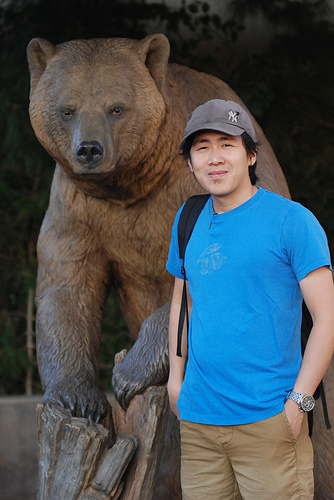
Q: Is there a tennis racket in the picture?
A: No, there are no rackets.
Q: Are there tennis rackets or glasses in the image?
A: No, there are no tennis rackets or glasses.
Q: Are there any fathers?
A: No, there are no fathers.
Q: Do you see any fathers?
A: No, there are no fathers.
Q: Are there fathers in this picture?
A: No, there are no fathers.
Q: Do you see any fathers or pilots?
A: No, there are no fathers or pilots.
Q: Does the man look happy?
A: Yes, the man is happy.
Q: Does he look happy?
A: Yes, the man is happy.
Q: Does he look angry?
A: No, the man is happy.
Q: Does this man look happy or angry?
A: The man is happy.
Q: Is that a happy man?
A: Yes, that is a happy man.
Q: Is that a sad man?
A: No, that is a happy man.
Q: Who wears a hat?
A: The man wears a hat.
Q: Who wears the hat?
A: The man wears a hat.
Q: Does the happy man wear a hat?
A: Yes, the man wears a hat.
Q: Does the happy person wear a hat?
A: Yes, the man wears a hat.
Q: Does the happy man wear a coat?
A: No, the man wears a hat.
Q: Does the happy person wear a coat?
A: No, the man wears a hat.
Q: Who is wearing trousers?
A: The man is wearing trousers.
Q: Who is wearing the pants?
A: The man is wearing trousers.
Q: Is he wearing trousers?
A: Yes, the man is wearing trousers.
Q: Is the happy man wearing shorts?
A: No, the man is wearing trousers.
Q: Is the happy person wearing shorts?
A: No, the man is wearing trousers.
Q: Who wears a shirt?
A: The man wears a shirt.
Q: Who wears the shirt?
A: The man wears a shirt.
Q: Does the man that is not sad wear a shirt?
A: Yes, the man wears a shirt.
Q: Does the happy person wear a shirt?
A: Yes, the man wears a shirt.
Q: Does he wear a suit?
A: No, the man wears a shirt.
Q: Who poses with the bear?
A: The man poses with the bear.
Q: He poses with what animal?
A: The man poses with the bear.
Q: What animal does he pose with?
A: The man poses with the bear.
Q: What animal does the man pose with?
A: The man poses with the bear.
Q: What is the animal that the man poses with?
A: The animal is a bear.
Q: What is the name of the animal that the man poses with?
A: The animal is a bear.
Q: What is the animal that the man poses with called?
A: The animal is a bear.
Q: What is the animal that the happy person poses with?
A: The animal is a bear.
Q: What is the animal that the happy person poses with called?
A: The animal is a bear.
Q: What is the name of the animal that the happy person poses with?
A: The animal is a bear.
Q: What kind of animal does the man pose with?
A: The man poses with the bear.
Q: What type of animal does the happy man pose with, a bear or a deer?
A: The man poses with a bear.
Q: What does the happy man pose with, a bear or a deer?
A: The man poses with a bear.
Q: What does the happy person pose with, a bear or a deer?
A: The man poses with a bear.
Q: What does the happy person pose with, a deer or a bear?
A: The man poses with a bear.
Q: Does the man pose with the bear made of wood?
A: Yes, the man poses with the bear.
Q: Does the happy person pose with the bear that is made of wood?
A: Yes, the man poses with the bear.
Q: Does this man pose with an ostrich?
A: No, the man poses with the bear.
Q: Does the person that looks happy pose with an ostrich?
A: No, the man poses with the bear.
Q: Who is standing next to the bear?
A: The man is standing next to the bear.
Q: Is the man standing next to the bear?
A: Yes, the man is standing next to the bear.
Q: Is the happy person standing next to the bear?
A: Yes, the man is standing next to the bear.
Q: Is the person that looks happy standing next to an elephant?
A: No, the man is standing next to the bear.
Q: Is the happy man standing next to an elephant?
A: No, the man is standing next to the bear.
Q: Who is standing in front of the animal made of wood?
A: The man is standing in front of the bear.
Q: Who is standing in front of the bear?
A: The man is standing in front of the bear.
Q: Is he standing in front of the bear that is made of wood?
A: Yes, the man is standing in front of the bear.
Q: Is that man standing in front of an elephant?
A: No, the man is standing in front of the bear.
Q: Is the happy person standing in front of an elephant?
A: No, the man is standing in front of the bear.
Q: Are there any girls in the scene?
A: No, there are no girls.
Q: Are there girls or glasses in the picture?
A: No, there are no girls or glasses.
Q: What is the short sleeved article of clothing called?
A: The clothing item is a shirt.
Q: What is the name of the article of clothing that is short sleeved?
A: The clothing item is a shirt.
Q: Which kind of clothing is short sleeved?
A: The clothing is a shirt.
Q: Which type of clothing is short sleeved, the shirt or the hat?
A: The shirt is short sleeved.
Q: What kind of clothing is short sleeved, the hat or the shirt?
A: The shirt is short sleeved.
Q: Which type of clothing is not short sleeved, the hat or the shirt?
A: The hat is not short sleeved.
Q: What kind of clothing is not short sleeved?
A: The clothing is a hat.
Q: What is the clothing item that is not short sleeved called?
A: The clothing item is a hat.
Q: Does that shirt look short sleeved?
A: Yes, the shirt is short sleeved.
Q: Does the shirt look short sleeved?
A: Yes, the shirt is short sleeved.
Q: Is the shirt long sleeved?
A: No, the shirt is short sleeved.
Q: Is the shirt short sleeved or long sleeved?
A: The shirt is short sleeved.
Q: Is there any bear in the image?
A: Yes, there is a bear.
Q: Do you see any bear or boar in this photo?
A: Yes, there is a bear.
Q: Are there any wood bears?
A: Yes, there is a wood bear.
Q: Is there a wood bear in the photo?
A: Yes, there is a wood bear.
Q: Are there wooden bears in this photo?
A: Yes, there is a wood bear.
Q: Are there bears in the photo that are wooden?
A: Yes, there is a bear that is wooden.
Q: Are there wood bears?
A: Yes, there is a bear that is made of wood.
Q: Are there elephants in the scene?
A: No, there are no elephants.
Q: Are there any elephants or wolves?
A: No, there are no elephants or wolves.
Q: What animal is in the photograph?
A: The animal is a bear.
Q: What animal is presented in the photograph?
A: The animal is a bear.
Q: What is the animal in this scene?
A: The animal is a bear.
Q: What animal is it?
A: The animal is a bear.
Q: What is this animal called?
A: That is a bear.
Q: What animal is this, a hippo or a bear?
A: That is a bear.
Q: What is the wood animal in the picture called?
A: The animal is a bear.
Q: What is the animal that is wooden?
A: The animal is a bear.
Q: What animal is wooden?
A: The animal is a bear.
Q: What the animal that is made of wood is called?
A: The animal is a bear.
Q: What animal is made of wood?
A: The animal is a bear.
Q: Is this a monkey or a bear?
A: This is a bear.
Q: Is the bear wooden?
A: Yes, the bear is wooden.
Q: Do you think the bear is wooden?
A: Yes, the bear is wooden.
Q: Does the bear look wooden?
A: Yes, the bear is wooden.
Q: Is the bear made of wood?
A: Yes, the bear is made of wood.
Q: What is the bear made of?
A: The bear is made of wood.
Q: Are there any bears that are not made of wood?
A: No, there is a bear but it is made of wood.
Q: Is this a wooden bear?
A: Yes, this is a wooden bear.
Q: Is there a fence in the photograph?
A: No, there are no fences.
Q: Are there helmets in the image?
A: No, there are no helmets.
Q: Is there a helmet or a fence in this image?
A: No, there are no helmets or fences.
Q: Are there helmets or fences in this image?
A: No, there are no helmets or fences.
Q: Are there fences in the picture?
A: No, there are no fences.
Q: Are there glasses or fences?
A: No, there are no fences or glasses.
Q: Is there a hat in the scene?
A: Yes, there is a hat.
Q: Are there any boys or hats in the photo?
A: Yes, there is a hat.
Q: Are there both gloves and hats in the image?
A: No, there is a hat but no gloves.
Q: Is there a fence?
A: No, there are no fences.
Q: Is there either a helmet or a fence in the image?
A: No, there are no fences or helmets.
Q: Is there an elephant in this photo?
A: No, there are no elephants.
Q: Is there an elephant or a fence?
A: No, there are no elephants or fences.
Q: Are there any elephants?
A: No, there are no elephants.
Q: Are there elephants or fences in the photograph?
A: No, there are no elephants or fences.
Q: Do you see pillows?
A: No, there are no pillows.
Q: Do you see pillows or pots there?
A: No, there are no pillows or pots.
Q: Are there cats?
A: No, there are no cats.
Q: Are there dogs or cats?
A: No, there are no cats or dogs.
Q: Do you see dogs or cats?
A: No, there are no cats or dogs.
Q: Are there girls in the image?
A: No, there are no girls.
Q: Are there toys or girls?
A: No, there are no girls or toys.